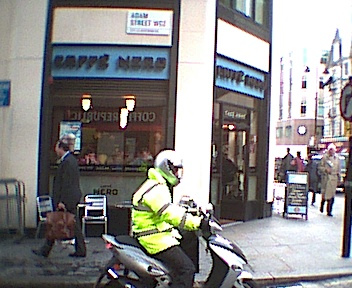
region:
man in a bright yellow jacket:
[92, 147, 237, 265]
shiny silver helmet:
[135, 132, 207, 209]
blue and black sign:
[38, 26, 211, 94]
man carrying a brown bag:
[33, 133, 96, 256]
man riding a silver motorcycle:
[86, 150, 266, 282]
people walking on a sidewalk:
[272, 130, 341, 228]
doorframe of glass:
[207, 75, 268, 238]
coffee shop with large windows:
[52, 95, 178, 176]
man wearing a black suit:
[19, 128, 111, 254]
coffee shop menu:
[276, 168, 314, 217]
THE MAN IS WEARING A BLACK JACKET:
[49, 150, 86, 218]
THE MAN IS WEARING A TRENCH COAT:
[317, 148, 344, 202]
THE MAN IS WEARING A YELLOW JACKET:
[125, 164, 211, 254]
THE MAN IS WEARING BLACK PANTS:
[146, 238, 198, 286]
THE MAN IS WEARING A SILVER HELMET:
[152, 143, 186, 190]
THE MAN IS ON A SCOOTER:
[91, 207, 253, 286]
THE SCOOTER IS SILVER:
[88, 199, 250, 286]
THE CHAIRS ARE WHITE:
[34, 186, 114, 238]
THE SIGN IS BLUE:
[49, 44, 174, 77]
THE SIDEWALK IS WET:
[2, 255, 130, 286]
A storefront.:
[48, 11, 281, 225]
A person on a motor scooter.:
[101, 142, 242, 282]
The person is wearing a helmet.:
[150, 138, 187, 187]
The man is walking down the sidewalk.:
[29, 126, 88, 256]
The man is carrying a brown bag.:
[32, 192, 81, 242]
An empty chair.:
[77, 189, 107, 239]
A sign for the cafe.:
[280, 164, 312, 221]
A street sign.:
[330, 69, 350, 269]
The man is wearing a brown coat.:
[315, 139, 342, 217]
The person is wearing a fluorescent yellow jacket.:
[119, 166, 207, 260]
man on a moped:
[93, 141, 256, 286]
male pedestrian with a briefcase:
[26, 135, 88, 261]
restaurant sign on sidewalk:
[277, 165, 312, 223]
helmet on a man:
[154, 146, 188, 187]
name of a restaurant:
[44, 48, 170, 80]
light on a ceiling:
[75, 95, 97, 111]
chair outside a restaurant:
[80, 189, 112, 240]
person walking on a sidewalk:
[307, 138, 346, 224]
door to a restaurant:
[217, 96, 262, 230]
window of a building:
[297, 96, 313, 120]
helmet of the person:
[139, 144, 190, 185]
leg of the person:
[155, 249, 196, 286]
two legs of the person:
[24, 228, 100, 260]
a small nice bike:
[68, 197, 269, 285]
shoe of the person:
[28, 243, 52, 258]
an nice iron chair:
[83, 169, 126, 251]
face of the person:
[46, 134, 73, 155]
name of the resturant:
[41, 37, 177, 93]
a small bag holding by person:
[34, 203, 88, 250]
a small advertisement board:
[270, 170, 315, 228]